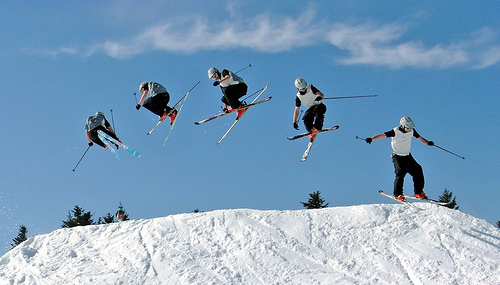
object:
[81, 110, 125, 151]
man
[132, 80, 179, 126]
man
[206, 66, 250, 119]
man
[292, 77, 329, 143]
man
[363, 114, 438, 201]
man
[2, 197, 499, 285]
snow